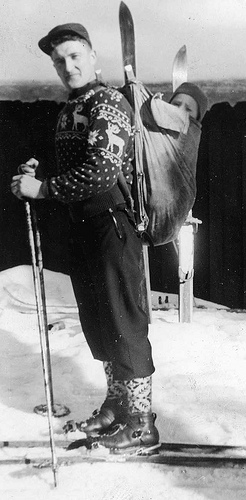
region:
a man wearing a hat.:
[26, 17, 115, 109]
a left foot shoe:
[64, 403, 174, 458]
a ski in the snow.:
[0, 450, 244, 465]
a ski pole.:
[12, 160, 70, 497]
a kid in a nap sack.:
[119, 62, 206, 248]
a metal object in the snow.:
[167, 196, 216, 328]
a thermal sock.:
[119, 371, 163, 423]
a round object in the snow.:
[34, 396, 69, 417]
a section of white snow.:
[86, 466, 146, 498]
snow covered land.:
[0, 75, 244, 103]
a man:
[40, 24, 189, 433]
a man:
[57, 115, 88, 255]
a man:
[90, 123, 175, 468]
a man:
[42, 66, 128, 459]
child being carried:
[155, 76, 214, 235]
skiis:
[109, 9, 144, 66]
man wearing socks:
[124, 382, 160, 414]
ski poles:
[30, 310, 54, 377]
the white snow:
[168, 338, 243, 405]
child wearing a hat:
[176, 83, 214, 98]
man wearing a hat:
[44, 27, 78, 36]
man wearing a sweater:
[66, 107, 131, 183]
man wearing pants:
[90, 236, 144, 309]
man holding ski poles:
[9, 173, 40, 207]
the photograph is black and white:
[10, 4, 245, 420]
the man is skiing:
[18, 13, 224, 412]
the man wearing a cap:
[19, 15, 210, 457]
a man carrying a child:
[25, 20, 235, 462]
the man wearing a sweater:
[8, 20, 210, 314]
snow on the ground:
[181, 320, 240, 428]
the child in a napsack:
[105, 64, 201, 254]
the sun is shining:
[149, 8, 233, 36]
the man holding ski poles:
[19, 17, 229, 378]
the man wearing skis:
[26, 20, 196, 478]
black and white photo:
[9, 19, 212, 175]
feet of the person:
[68, 385, 163, 448]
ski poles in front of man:
[18, 212, 54, 245]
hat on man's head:
[45, 19, 87, 49]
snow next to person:
[101, 465, 132, 488]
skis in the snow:
[154, 418, 235, 485]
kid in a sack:
[168, 77, 213, 120]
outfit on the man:
[62, 98, 121, 172]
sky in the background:
[209, 19, 225, 38]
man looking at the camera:
[32, 32, 109, 98]